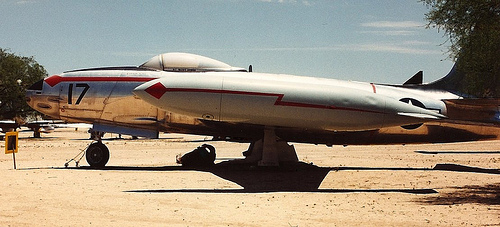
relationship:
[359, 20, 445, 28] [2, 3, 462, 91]
cloud in sky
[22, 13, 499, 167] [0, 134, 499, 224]
airplane on sand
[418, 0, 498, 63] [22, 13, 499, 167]
vegetation behind airplane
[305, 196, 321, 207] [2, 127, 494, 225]
rock on ground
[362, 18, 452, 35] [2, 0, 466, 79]
cloud in sky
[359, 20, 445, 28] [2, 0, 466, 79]
cloud in sky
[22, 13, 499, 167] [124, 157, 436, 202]
airplane casts shadow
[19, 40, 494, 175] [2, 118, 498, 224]
airplane on sand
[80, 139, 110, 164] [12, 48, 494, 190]
wheel on plane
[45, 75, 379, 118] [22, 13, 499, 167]
red stripes on airplane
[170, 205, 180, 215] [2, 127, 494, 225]
rock on ground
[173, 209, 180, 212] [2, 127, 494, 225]
rock on ground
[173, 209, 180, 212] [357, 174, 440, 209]
rock on ground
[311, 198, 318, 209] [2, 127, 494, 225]
rock on ground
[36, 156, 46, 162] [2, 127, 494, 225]
rock on ground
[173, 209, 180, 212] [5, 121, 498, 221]
rock on ground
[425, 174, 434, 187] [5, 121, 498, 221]
rock on ground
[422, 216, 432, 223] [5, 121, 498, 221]
rock on ground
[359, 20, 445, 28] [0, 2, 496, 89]
cloud in sky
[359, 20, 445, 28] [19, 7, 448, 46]
cloud in sky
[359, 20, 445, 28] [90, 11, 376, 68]
cloud in sky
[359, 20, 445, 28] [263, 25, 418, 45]
cloud in sky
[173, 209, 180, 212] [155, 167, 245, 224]
rock on ground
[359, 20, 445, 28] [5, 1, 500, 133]
cloud in sky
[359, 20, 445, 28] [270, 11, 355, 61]
cloud are in sky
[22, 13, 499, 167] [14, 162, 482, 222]
airplane on ground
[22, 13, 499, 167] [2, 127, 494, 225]
airplane on ground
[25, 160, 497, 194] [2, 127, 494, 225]
shadow on ground